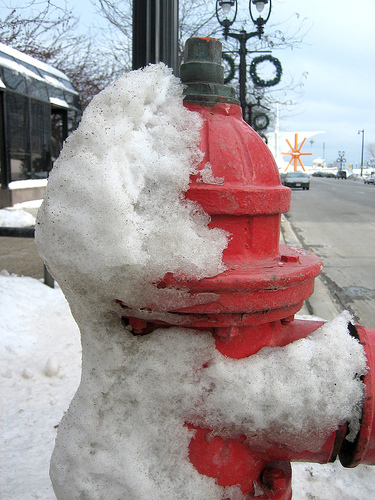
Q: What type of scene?
A: Outdoor.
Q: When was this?
A: Daytime.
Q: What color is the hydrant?
A: Orange.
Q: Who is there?
A: No one.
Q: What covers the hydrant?
A: Snow.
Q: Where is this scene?
A: Street.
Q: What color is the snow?
A: White.